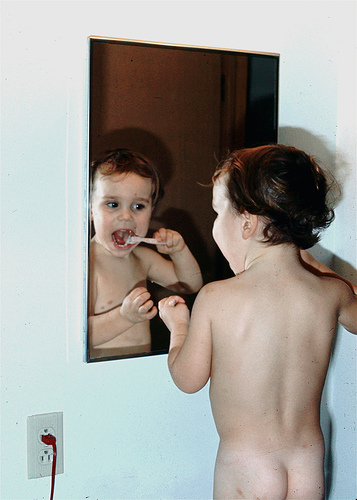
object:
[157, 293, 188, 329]
hand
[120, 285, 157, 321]
hand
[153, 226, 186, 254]
hand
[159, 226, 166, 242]
finger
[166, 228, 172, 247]
finger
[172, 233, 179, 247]
finger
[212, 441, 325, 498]
butt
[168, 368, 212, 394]
elbow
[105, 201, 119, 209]
eye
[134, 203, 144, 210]
eye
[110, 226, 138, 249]
mouth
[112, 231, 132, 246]
teeth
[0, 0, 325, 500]
wall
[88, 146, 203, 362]
toddler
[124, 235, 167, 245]
toothbrush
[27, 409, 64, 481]
outlet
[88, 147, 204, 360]
reflection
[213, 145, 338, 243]
hair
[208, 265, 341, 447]
back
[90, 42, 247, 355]
door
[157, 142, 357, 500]
child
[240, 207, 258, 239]
ear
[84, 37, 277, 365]
mirror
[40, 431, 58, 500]
plug